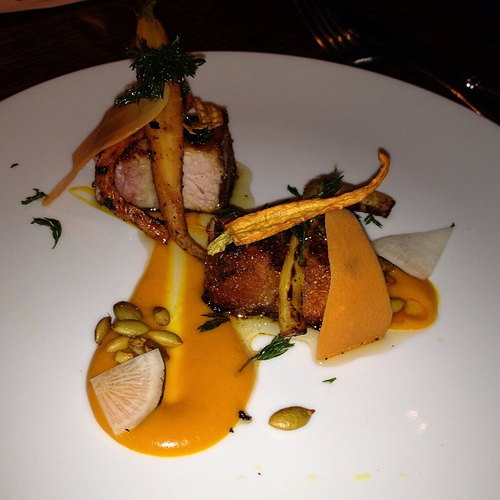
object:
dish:
[1, 51, 498, 498]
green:
[320, 377, 336, 385]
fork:
[310, 21, 499, 124]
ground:
[422, 112, 462, 161]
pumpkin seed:
[113, 301, 141, 321]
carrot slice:
[137, 14, 207, 263]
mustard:
[88, 222, 255, 457]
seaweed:
[109, 39, 203, 112]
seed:
[388, 296, 407, 314]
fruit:
[87, 346, 169, 436]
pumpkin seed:
[269, 407, 315, 429]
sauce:
[82, 58, 263, 458]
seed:
[148, 327, 184, 348]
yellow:
[343, 260, 373, 305]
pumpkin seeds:
[129, 336, 171, 360]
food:
[41, 24, 457, 457]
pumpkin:
[316, 205, 394, 361]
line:
[150, 240, 193, 406]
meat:
[110, 95, 236, 209]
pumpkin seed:
[153, 305, 171, 328]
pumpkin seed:
[94, 316, 114, 343]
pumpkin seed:
[111, 317, 151, 338]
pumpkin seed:
[113, 346, 134, 365]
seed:
[105, 334, 130, 354]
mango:
[315, 205, 394, 362]